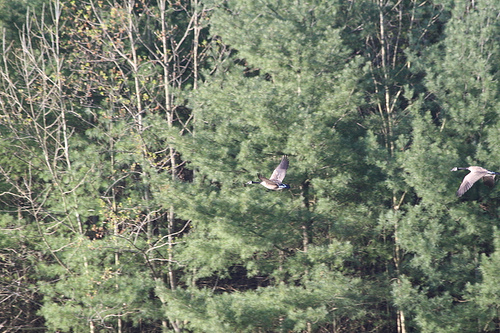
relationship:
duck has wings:
[248, 155, 292, 194] [269, 156, 290, 182]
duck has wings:
[248, 155, 292, 194] [254, 171, 279, 191]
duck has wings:
[451, 162, 497, 200] [455, 171, 484, 197]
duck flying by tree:
[248, 155, 292, 194] [374, 11, 500, 332]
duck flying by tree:
[248, 155, 292, 194] [132, 0, 392, 332]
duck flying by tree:
[451, 162, 497, 200] [374, 11, 500, 332]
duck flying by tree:
[451, 162, 497, 200] [132, 0, 392, 332]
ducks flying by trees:
[245, 155, 500, 199] [0, 0, 499, 332]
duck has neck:
[451, 162, 497, 200] [456, 162, 467, 173]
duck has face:
[451, 162, 497, 200] [449, 164, 459, 176]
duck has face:
[248, 155, 292, 194] [245, 177, 253, 187]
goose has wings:
[241, 157, 294, 198] [269, 156, 290, 182]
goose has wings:
[241, 157, 294, 198] [254, 171, 279, 191]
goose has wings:
[449, 159, 496, 199] [455, 171, 484, 197]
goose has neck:
[449, 159, 496, 199] [456, 162, 467, 173]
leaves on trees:
[6, 4, 180, 122] [0, 0, 499, 332]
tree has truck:
[132, 0, 392, 332] [298, 168, 319, 332]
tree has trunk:
[132, 0, 392, 332] [297, 168, 315, 332]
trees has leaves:
[0, 0, 499, 332] [6, 4, 180, 122]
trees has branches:
[0, 0, 499, 332] [3, 9, 175, 285]